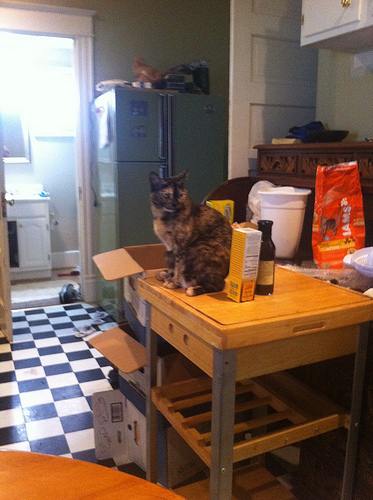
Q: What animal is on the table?
A: Cat.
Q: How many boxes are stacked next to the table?
A: Three.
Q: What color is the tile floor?
A: Black and white.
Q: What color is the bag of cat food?
A: Orange.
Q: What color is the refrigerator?
A: Green.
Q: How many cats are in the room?
A: One.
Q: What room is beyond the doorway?
A: Bathroom.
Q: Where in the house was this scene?
A: The kitchen.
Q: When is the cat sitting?
A: On the cart.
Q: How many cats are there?
A: 1.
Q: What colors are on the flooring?
A: Black and white.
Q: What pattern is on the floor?
A: Checker.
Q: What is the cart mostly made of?
A: Wood.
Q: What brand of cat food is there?
A: Iams.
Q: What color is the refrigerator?
A: Green.